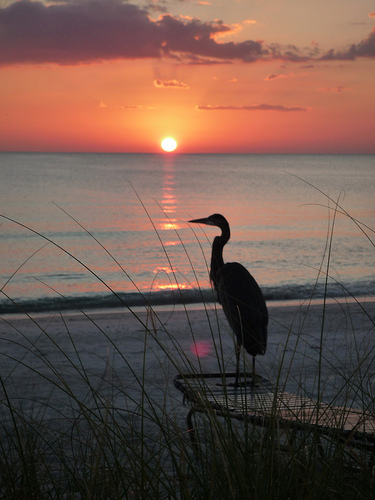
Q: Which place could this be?
A: It is a beach.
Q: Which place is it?
A: It is a beach.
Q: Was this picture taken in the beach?
A: Yes, it was taken in the beach.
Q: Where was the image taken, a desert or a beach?
A: It was taken at a beach.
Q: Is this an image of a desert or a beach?
A: It is showing a beach.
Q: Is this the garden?
A: No, it is the beach.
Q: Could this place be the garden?
A: No, it is the beach.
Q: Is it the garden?
A: No, it is the beach.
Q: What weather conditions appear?
A: It is cloudy.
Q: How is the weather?
A: It is cloudy.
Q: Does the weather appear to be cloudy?
A: Yes, it is cloudy.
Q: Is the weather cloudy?
A: Yes, it is cloudy.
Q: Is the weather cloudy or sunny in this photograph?
A: It is cloudy.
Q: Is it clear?
A: No, it is cloudy.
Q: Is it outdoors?
A: Yes, it is outdoors.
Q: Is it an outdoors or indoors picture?
A: It is outdoors.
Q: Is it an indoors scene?
A: No, it is outdoors.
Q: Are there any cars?
A: No, there are no cars.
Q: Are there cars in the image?
A: No, there are no cars.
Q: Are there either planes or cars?
A: No, there are no cars or planes.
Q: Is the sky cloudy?
A: Yes, the sky is cloudy.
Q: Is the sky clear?
A: No, the sky is cloudy.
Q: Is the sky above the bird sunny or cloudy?
A: The sky is cloudy.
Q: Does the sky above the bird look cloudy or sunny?
A: The sky is cloudy.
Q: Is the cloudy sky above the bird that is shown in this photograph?
A: Yes, the sky is above the bird.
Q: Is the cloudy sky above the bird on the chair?
A: Yes, the sky is above the bird.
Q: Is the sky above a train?
A: No, the sky is above the bird.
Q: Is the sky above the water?
A: Yes, the sky is above the water.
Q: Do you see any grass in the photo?
A: Yes, there is grass.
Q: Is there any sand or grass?
A: Yes, there is grass.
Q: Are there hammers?
A: No, there are no hammers.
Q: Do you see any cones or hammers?
A: No, there are no hammers or cones.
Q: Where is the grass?
A: The grass is on the beach.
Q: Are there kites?
A: No, there are no kites.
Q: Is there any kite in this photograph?
A: No, there are no kites.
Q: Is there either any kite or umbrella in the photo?
A: No, there are no kites or umbrellas.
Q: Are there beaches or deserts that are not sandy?
A: No, there is a beach but it is sandy.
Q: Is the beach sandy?
A: Yes, the beach is sandy.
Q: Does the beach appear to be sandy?
A: Yes, the beach is sandy.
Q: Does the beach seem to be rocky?
A: No, the beach is sandy.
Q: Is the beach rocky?
A: No, the beach is sandy.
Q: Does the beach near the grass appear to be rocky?
A: No, the beach is sandy.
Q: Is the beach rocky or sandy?
A: The beach is sandy.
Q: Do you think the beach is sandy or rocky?
A: The beach is sandy.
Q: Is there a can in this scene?
A: No, there are no cans.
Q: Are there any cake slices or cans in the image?
A: No, there are no cans or cake slices.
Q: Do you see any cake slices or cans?
A: No, there are no cans or cake slices.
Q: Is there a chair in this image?
A: Yes, there is a chair.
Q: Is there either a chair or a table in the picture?
A: Yes, there is a chair.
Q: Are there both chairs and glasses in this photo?
A: No, there is a chair but no glasses.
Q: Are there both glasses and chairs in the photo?
A: No, there is a chair but no glasses.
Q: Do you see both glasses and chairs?
A: No, there is a chair but no glasses.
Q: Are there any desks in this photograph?
A: No, there are no desks.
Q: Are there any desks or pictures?
A: No, there are no desks or pictures.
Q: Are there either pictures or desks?
A: No, there are no desks or pictures.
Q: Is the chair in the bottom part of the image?
A: Yes, the chair is in the bottom of the image.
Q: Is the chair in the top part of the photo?
A: No, the chair is in the bottom of the image.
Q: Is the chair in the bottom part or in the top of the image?
A: The chair is in the bottom of the image.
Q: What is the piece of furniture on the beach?
A: The piece of furniture is a chair.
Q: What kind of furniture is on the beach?
A: The piece of furniture is a chair.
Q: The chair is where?
A: The chair is on the beach.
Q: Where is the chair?
A: The chair is on the beach.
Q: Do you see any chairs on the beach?
A: Yes, there is a chair on the beach.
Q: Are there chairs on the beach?
A: Yes, there is a chair on the beach.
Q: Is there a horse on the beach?
A: No, there is a chair on the beach.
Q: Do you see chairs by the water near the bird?
A: Yes, there is a chair by the water.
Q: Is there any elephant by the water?
A: No, there is a chair by the water.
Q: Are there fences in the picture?
A: No, there are no fences.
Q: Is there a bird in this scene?
A: Yes, there is a bird.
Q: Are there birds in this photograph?
A: Yes, there is a bird.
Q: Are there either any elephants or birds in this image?
A: Yes, there is a bird.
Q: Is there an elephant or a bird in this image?
A: Yes, there is a bird.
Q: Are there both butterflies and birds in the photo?
A: No, there is a bird but no butterflies.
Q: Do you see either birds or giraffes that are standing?
A: Yes, the bird is standing.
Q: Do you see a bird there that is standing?
A: Yes, there is a bird that is standing.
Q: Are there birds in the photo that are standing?
A: Yes, there is a bird that is standing.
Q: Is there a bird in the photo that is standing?
A: Yes, there is a bird that is standing.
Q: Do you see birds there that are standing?
A: Yes, there is a bird that is standing.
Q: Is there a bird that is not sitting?
A: Yes, there is a bird that is standing.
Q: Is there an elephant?
A: No, there are no elephants.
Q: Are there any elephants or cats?
A: No, there are no elephants or cats.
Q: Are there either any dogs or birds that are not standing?
A: No, there is a bird but it is standing.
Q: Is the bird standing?
A: Yes, the bird is standing.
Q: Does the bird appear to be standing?
A: Yes, the bird is standing.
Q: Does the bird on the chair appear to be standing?
A: Yes, the bird is standing.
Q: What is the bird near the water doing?
A: The bird is standing.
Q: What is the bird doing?
A: The bird is standing.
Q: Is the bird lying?
A: No, the bird is standing.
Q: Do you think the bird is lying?
A: No, the bird is standing.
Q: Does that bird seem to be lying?
A: No, the bird is standing.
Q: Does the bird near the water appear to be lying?
A: No, the bird is standing.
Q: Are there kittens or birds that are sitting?
A: No, there is a bird but it is standing.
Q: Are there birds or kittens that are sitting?
A: No, there is a bird but it is standing.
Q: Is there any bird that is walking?
A: No, there is a bird but it is standing.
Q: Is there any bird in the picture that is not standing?
A: No, there is a bird but it is standing.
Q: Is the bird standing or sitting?
A: The bird is standing.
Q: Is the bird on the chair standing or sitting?
A: The bird is standing.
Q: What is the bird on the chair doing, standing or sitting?
A: The bird is standing.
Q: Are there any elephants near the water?
A: No, there is a bird near the water.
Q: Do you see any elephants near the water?
A: No, there is a bird near the water.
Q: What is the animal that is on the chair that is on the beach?
A: The animal is a bird.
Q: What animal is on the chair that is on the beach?
A: The animal is a bird.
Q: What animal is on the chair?
A: The animal is a bird.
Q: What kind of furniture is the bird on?
A: The bird is on the chair.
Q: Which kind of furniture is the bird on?
A: The bird is on the chair.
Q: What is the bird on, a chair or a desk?
A: The bird is on a chair.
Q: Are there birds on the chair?
A: Yes, there is a bird on the chair.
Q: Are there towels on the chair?
A: No, there is a bird on the chair.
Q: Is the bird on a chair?
A: Yes, the bird is on a chair.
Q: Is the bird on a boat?
A: No, the bird is on a chair.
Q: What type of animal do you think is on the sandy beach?
A: The animal is a bird.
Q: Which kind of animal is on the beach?
A: The animal is a bird.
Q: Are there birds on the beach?
A: Yes, there is a bird on the beach.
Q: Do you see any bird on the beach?
A: Yes, there is a bird on the beach.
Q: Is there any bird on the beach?
A: Yes, there is a bird on the beach.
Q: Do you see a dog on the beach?
A: No, there is a bird on the beach.